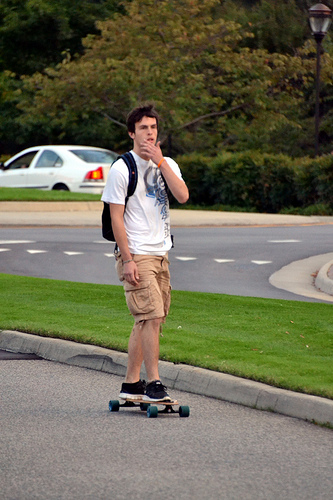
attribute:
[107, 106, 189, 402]
boy — young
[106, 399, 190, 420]
skateboard — under, white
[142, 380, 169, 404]
tennis shoes — black, white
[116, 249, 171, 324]
shorts — tan, brown, khaki, cargo shorts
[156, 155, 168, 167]
band — around wrist, orange, yellow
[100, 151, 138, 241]
backpack — black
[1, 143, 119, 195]
car — white, parked, driving away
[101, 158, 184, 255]
t-shirt — white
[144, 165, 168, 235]
design — gray, blue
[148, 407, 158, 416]
wheels — blue, green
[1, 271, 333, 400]
grass — short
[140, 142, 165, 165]
hand — on face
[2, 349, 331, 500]
road — gray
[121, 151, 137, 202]
strap — black, blue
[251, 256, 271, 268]
triangles — white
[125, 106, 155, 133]
hair — dark